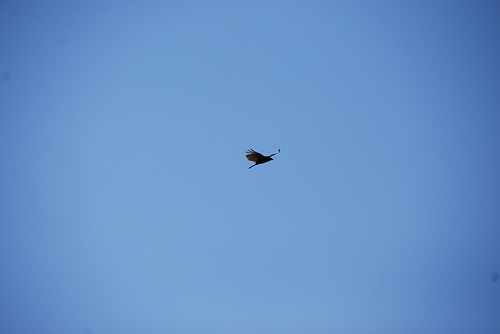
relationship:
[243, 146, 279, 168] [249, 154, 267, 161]
bird with feathers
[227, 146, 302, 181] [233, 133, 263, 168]
bird with feathers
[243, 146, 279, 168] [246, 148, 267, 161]
bird has wing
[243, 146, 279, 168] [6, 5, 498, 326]
bird flying through sky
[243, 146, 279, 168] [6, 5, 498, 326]
bird in sky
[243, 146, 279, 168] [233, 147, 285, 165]
bird with feathers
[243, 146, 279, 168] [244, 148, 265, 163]
bird with wing